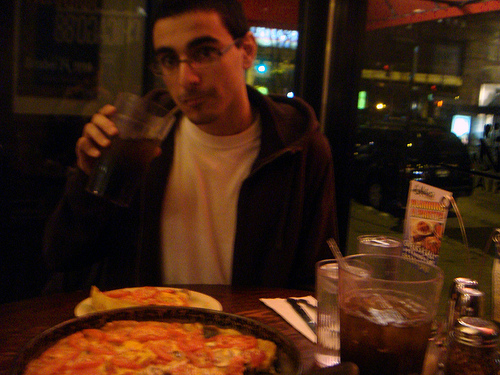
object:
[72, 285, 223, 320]
plate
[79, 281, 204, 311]
sliced pizza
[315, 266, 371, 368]
water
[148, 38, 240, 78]
glasses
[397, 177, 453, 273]
small sign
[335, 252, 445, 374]
glass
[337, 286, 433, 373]
soda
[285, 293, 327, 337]
silverware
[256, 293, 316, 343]
napkin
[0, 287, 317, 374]
table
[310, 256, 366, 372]
glass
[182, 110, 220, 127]
facial hair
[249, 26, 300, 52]
window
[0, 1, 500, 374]
restaurant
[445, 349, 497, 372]
red pepper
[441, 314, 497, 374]
jar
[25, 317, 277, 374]
pizza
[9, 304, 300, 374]
tray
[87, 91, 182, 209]
cup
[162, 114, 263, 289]
shirt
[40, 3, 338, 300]
man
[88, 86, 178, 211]
drink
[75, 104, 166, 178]
hand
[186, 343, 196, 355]
tomatoes